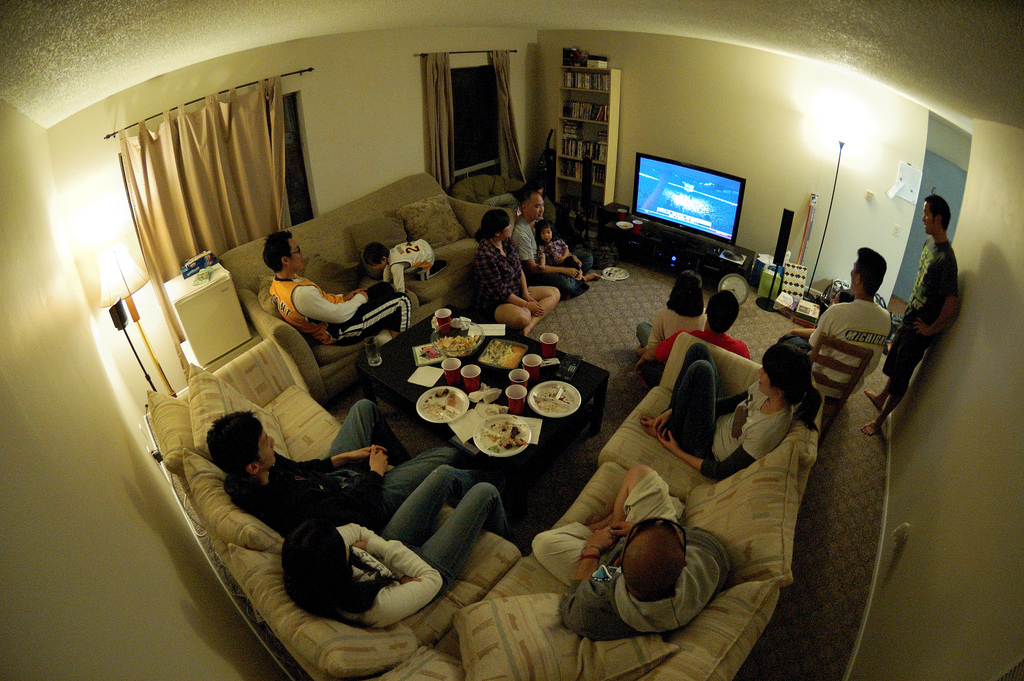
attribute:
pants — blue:
[373, 456, 527, 591]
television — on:
[624, 139, 750, 265]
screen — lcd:
[628, 150, 745, 256]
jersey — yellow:
[261, 260, 348, 345]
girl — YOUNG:
[541, 217, 574, 263]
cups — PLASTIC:
[415, 338, 582, 444]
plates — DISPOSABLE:
[409, 333, 587, 446]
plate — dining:
[405, 379, 472, 423]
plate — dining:
[522, 368, 589, 423]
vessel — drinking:
[437, 351, 470, 384]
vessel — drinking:
[459, 353, 483, 384]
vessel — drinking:
[500, 379, 533, 406]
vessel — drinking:
[500, 359, 533, 385]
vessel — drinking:
[517, 342, 544, 369]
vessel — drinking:
[532, 325, 576, 352]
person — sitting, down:
[254, 217, 421, 351]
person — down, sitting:
[655, 340, 830, 475]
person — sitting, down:
[785, 247, 894, 407]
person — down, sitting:
[863, 203, 946, 426]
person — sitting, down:
[656, 279, 734, 368]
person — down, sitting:
[627, 264, 712, 347]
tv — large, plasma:
[607, 111, 787, 326]